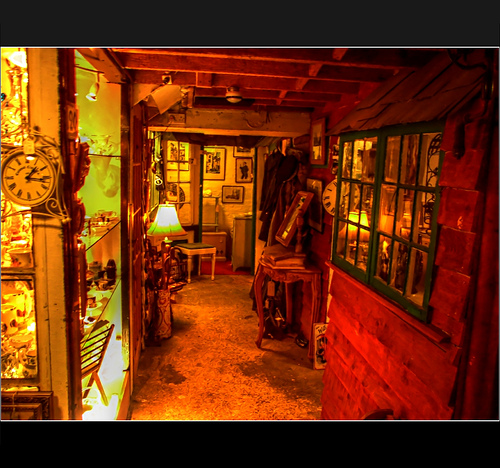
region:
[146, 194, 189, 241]
lamp on the side of the hallway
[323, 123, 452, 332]
green framed window panes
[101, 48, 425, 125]
wooden beams of the ceiling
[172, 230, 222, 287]
green covered stool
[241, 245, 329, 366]
fancy end table against a wall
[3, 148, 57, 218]
white clock on a white door frame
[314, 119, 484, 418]
siding on a wall holding a window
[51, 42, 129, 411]
glass shelf with lighting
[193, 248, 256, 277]
red carpet in an adjacent room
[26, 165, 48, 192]
black hands on a white clock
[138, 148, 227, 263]
a light in a room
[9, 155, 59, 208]
a clock in a room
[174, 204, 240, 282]
a chair in a room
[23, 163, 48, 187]
the hands on a clock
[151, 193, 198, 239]
a lamp shade on a light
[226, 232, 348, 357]
a table in a room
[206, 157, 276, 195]
a picture on a wall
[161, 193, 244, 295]
a light near a chair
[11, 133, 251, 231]
a clock near a light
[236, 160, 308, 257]
a coat hanging in a room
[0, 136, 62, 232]
round analog clock on wall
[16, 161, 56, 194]
hands on analog clock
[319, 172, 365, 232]
round analog clock on wall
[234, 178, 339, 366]
small stand with stuff on top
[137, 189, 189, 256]
light green lamp shade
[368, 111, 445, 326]
green frame of window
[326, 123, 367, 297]
green frame of window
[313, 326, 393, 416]
wooden panels on wall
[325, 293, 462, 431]
wooden panels on wall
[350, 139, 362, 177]
pane of the window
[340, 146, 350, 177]
pane of the window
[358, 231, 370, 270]
pane of the window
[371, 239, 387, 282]
pane of the window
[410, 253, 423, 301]
pane of the window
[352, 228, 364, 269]
pane of the window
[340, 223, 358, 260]
pane of the window